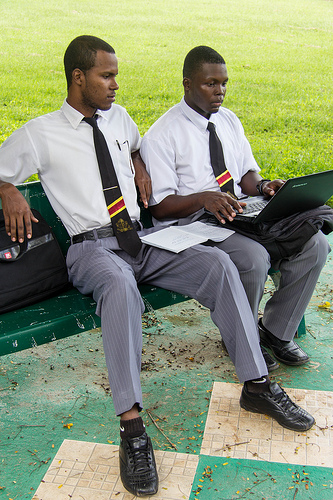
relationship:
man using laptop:
[139, 45, 331, 372] [202, 169, 331, 235]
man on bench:
[139, 45, 331, 372] [1, 180, 195, 356]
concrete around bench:
[0, 232, 331, 499] [1, 180, 195, 356]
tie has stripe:
[81, 114, 143, 260] [106, 195, 127, 218]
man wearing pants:
[139, 45, 331, 372] [208, 231, 330, 343]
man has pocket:
[0, 35, 315, 499] [116, 143, 136, 179]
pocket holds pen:
[116, 143, 136, 179] [114, 139, 122, 152]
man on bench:
[0, 35, 315, 499] [1, 180, 195, 356]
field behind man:
[1, 1, 332, 206] [139, 45, 331, 372]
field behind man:
[1, 1, 332, 206] [0, 35, 315, 499]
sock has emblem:
[118, 416, 146, 441] [118, 426, 126, 432]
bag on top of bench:
[0, 208, 69, 315] [1, 180, 195, 356]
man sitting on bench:
[139, 45, 331, 372] [1, 180, 195, 356]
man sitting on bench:
[0, 35, 315, 499] [1, 180, 195, 356]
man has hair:
[139, 45, 331, 372] [182, 45, 225, 76]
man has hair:
[0, 35, 315, 499] [63, 34, 116, 88]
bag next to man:
[0, 208, 69, 315] [0, 35, 315, 499]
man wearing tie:
[0, 35, 315, 499] [81, 114, 143, 260]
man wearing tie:
[139, 45, 331, 372] [207, 122, 238, 200]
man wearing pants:
[0, 35, 315, 499] [64, 221, 269, 416]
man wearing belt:
[0, 35, 315, 499] [68, 220, 155, 244]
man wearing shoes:
[139, 45, 331, 372] [221, 318, 309, 371]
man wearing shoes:
[0, 35, 315, 499] [118, 381, 314, 498]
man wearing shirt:
[139, 45, 331, 372] [138, 97, 261, 227]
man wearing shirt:
[0, 35, 315, 499] [0, 97, 143, 237]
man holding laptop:
[139, 45, 331, 372] [202, 169, 331, 235]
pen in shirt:
[114, 139, 122, 152] [0, 97, 143, 237]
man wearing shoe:
[0, 35, 315, 499] [118, 429, 160, 497]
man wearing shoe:
[0, 35, 315, 499] [239, 380, 318, 433]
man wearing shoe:
[139, 45, 331, 372] [220, 338, 281, 371]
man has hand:
[139, 45, 331, 372] [204, 191, 247, 224]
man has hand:
[0, 35, 315, 499] [0, 186, 40, 246]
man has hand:
[139, 45, 331, 372] [261, 178, 285, 196]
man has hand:
[0, 35, 315, 499] [135, 170, 153, 208]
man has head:
[139, 45, 331, 372] [181, 45, 230, 114]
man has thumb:
[0, 35, 315, 499] [29, 210, 41, 223]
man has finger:
[139, 45, 331, 372] [212, 210, 226, 224]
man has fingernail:
[139, 45, 331, 372] [219, 218, 226, 226]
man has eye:
[139, 45, 331, 372] [205, 80, 215, 89]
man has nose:
[0, 35, 315, 499] [109, 78, 120, 91]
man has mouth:
[139, 45, 331, 372] [209, 98, 223, 108]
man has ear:
[0, 35, 315, 499] [71, 67, 83, 88]